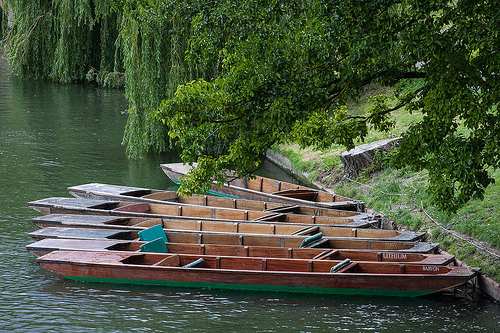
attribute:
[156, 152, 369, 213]
boats — wooden, wood, long, narrow, floating, angled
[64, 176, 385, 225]
boats — wooden, wood, long, narrow, floating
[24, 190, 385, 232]
boats — wooden, wood, long, narrow, floating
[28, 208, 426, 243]
boats — wooden, wood, long, narrow, floating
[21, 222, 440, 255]
boats — wooden, wood, long, narrow, floating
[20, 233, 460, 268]
boats — wooden, wood, long, narrow, floating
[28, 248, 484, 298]
boats — wooden, wood, long, narrow, floating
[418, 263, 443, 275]
letters — white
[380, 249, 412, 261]
letters — white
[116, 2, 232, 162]
tree — hanging, overgrown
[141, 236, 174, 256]
seats — blue, green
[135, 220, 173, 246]
seats — blue, green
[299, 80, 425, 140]
limbs — hanging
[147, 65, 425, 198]
limbs — hanging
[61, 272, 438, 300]
stripe — green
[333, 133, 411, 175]
stump — large, thick